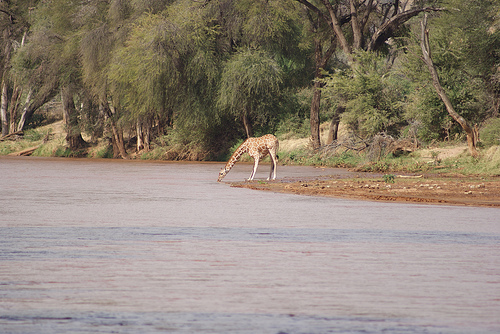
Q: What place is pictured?
A: It is a lake.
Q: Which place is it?
A: It is a lake.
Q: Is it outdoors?
A: Yes, it is outdoors.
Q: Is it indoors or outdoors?
A: It is outdoors.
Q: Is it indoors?
A: No, it is outdoors.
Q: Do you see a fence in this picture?
A: No, there are no fences.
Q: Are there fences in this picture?
A: No, there are no fences.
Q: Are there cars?
A: No, there are no cars.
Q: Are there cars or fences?
A: No, there are no cars or fences.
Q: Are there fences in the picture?
A: No, there are no fences.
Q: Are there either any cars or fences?
A: No, there are no fences or cars.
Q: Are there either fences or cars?
A: No, there are no fences or cars.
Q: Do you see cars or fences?
A: No, there are no fences or cars.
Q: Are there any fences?
A: No, there are no fences.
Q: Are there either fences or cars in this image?
A: No, there are no fences or cars.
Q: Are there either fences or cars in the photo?
A: No, there are no fences or cars.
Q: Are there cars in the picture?
A: No, there are no cars.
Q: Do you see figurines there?
A: No, there are no figurines.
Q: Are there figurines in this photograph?
A: No, there are no figurines.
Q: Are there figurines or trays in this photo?
A: No, there are no figurines or trays.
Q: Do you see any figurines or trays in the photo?
A: No, there are no figurines or trays.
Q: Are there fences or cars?
A: No, there are no fences or cars.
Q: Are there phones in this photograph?
A: Yes, there is a phone.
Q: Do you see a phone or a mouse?
A: Yes, there is a phone.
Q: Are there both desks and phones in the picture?
A: No, there is a phone but no desks.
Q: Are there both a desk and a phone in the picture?
A: No, there is a phone but no desks.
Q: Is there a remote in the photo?
A: No, there are no remote controls.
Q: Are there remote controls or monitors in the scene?
A: No, there are no remote controls or monitors.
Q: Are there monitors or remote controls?
A: No, there are no remote controls or monitors.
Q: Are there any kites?
A: No, there are no kites.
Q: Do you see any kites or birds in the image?
A: No, there are no kites or birds.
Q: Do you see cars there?
A: No, there are no cars.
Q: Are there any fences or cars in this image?
A: No, there are no cars or fences.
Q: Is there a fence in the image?
A: No, there are no fences.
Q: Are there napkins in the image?
A: No, there are no napkins.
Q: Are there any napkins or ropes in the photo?
A: No, there are no napkins or ropes.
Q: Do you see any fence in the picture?
A: No, there are no fences.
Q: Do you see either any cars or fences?
A: No, there are no fences or cars.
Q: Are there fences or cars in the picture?
A: No, there are no fences or cars.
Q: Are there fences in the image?
A: No, there are no fences.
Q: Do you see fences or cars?
A: No, there are no fences or cars.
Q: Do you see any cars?
A: No, there are no cars.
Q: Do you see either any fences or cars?
A: No, there are no cars or fences.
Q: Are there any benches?
A: No, there are no benches.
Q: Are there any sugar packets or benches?
A: No, there are no benches or sugar packets.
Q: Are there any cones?
A: No, there are no cones.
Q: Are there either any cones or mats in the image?
A: No, there are no cones or mats.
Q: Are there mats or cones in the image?
A: No, there are no cones or mats.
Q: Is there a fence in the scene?
A: No, there are no fences.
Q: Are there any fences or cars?
A: No, there are no fences or cars.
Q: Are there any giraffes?
A: Yes, there is a giraffe.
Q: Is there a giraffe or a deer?
A: Yes, there is a giraffe.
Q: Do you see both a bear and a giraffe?
A: No, there is a giraffe but no bears.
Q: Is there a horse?
A: No, there are no horses.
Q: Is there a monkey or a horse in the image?
A: No, there are no horses or monkeys.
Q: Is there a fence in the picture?
A: No, there are no fences.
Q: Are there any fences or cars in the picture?
A: No, there are no fences or cars.